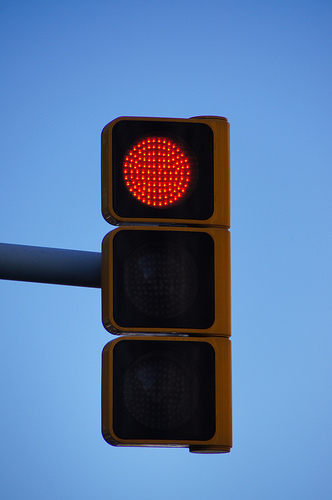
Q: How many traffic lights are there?
A: 1.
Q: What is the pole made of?
A: Steel.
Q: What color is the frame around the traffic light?
A: Yellow.